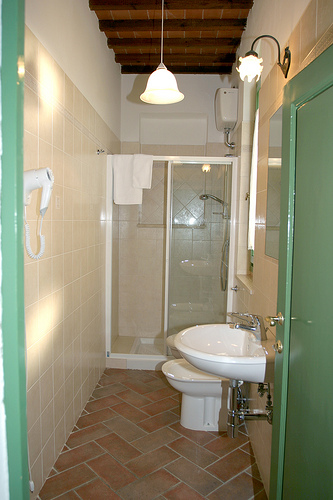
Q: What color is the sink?
A: White.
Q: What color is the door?
A: Green.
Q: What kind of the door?
A: Glass.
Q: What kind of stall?
A: Glass.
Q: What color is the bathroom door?
A: Sea green.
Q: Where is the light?
A: Light hanging from ceiling.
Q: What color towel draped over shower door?
A: White.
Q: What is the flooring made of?
A: Tiles.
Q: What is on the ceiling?
A: Wooden bars.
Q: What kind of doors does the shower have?
A: Glass.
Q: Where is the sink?
A: Next to the toilet.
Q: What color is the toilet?
A: White.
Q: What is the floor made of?
A: Tile.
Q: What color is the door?
A: Green.